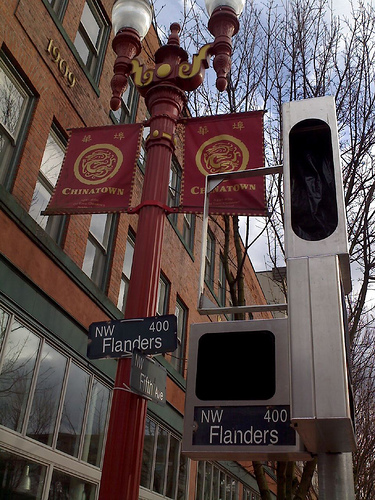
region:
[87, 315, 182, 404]
two street signs on a red pole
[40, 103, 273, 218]
two red and gold flags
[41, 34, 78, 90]
gold numbers on a red brick building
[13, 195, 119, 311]
green wood trim on a brick building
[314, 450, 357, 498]
metal pole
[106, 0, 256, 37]
two glass lamps atop a red pole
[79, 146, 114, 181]
golden dragon on a red flag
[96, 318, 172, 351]
white lettering on a black sign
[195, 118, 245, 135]
gold Chinese characters on a red flag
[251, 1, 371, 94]
bare tree branches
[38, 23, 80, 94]
1909 in gold on building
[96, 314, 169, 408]
street signs on red pole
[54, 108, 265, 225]
red chinatown banners on pole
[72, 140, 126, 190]
gold dragon on red banner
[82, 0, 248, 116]
two lamps on red pole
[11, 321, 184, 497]
row of windows on building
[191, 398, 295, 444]
NW 400 Flanders on street sign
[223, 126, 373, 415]
tree with no leaves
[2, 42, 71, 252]
green molding on windows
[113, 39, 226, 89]
gold details on red pole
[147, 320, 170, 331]
white text reading 400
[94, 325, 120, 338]
white text reading NW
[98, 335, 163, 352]
white text reading Flanders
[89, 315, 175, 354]
blue sign reading NW 400 Flanders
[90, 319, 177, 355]
blue street sign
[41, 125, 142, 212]
burgundy Chinatown banner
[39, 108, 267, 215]
two burgundy Chinatown banners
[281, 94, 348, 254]
silver object with a black center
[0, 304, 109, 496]
windows on a building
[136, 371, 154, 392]
white text reading Fifth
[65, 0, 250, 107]
Red and yellow street lights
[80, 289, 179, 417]
Two street signs on a pole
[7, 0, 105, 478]
Tall building with windows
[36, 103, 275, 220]
Signs for Chinatown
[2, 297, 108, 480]
Windows in a building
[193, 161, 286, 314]
Empty metal sign holder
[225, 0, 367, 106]
Trees with no leaves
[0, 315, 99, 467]
Reflection in the windows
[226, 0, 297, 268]
Cloudy sky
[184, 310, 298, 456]
Blank cross walk signal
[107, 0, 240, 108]
a street light on the sidewalk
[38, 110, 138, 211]
a Chinatown banner on the street light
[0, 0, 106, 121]
a brick building next to the street light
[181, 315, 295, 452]
an infromation box next to the street light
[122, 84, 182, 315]
the street light post is painted red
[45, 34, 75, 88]
the numbers 1909 on the side of the building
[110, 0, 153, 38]
the glass globe on the street light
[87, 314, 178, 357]
a black street sign for NW Flanders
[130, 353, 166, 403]
a street sign for Fifth Ave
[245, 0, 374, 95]
a deciduous tree without its leaves